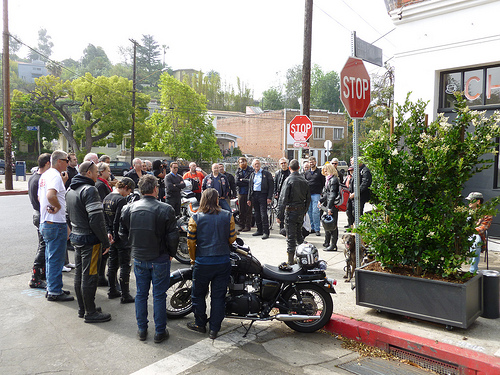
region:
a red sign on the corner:
[336, 48, 373, 256]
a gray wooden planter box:
[355, 270, 458, 321]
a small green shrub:
[355, 105, 465, 271]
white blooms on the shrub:
[414, 114, 453, 157]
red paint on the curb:
[351, 316, 386, 345]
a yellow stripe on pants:
[87, 247, 100, 275]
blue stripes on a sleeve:
[186, 229, 197, 239]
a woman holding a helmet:
[320, 160, 345, 243]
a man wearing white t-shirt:
[44, 148, 74, 295]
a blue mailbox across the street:
[15, 158, 29, 190]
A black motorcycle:
[163, 241, 325, 324]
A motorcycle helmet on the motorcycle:
[291, 235, 320, 270]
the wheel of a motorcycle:
[169, 231, 201, 259]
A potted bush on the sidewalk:
[364, 103, 484, 329]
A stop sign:
[327, 52, 371, 282]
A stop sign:
[286, 100, 313, 196]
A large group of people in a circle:
[33, 137, 368, 317]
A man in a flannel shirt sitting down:
[453, 182, 495, 268]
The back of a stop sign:
[317, 134, 337, 162]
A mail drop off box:
[10, 157, 28, 184]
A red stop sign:
[330, 47, 383, 132]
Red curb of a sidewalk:
[321, 301, 481, 373]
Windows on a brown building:
[308, 117, 348, 154]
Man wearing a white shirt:
[31, 148, 76, 223]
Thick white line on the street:
[135, 330, 267, 370]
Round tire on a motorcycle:
[279, 275, 337, 336]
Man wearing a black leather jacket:
[119, 177, 184, 266]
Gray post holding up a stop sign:
[341, 115, 376, 278]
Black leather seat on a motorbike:
[257, 253, 308, 287]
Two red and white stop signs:
[269, 49, 379, 150]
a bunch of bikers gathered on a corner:
[11, 119, 378, 314]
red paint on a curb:
[308, 298, 498, 373]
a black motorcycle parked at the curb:
[162, 219, 344, 347]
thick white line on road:
[98, 316, 304, 371]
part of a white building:
[375, 3, 499, 270]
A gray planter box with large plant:
[351, 99, 499, 332]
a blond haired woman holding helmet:
[311, 154, 348, 265]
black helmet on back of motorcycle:
[291, 241, 333, 278]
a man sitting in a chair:
[438, 192, 498, 272]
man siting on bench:
[463, 197, 480, 291]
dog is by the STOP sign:
[338, 232, 401, 306]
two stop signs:
[263, 69, 404, 149]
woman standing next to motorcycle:
[182, 192, 270, 369]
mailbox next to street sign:
[6, 157, 31, 185]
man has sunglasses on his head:
[90, 158, 96, 172]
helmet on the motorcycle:
[287, 230, 348, 281]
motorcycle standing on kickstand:
[222, 304, 272, 354]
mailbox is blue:
[11, 147, 39, 192]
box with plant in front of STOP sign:
[340, 129, 480, 346]